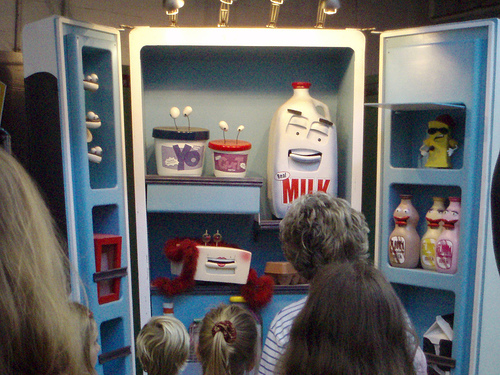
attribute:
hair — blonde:
[196, 301, 260, 374]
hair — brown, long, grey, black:
[274, 259, 417, 374]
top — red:
[290, 80, 314, 90]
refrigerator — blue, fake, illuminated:
[19, 17, 500, 374]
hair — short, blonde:
[277, 185, 372, 283]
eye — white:
[285, 113, 312, 141]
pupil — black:
[294, 130, 301, 136]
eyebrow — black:
[286, 108, 304, 119]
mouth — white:
[288, 148, 322, 164]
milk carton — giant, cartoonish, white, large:
[263, 79, 340, 221]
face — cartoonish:
[282, 105, 335, 174]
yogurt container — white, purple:
[154, 104, 210, 179]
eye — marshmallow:
[183, 104, 194, 131]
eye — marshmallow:
[167, 104, 181, 132]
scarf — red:
[150, 235, 277, 312]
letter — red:
[282, 176, 300, 207]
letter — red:
[300, 176, 309, 202]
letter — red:
[308, 179, 314, 199]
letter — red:
[315, 178, 333, 197]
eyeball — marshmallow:
[218, 118, 230, 143]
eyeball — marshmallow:
[234, 123, 248, 144]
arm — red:
[156, 237, 202, 297]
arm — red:
[242, 268, 276, 306]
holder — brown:
[211, 319, 238, 345]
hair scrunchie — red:
[211, 317, 239, 347]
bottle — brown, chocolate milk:
[386, 190, 422, 271]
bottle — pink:
[434, 191, 461, 274]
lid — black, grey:
[151, 126, 213, 144]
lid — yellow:
[430, 192, 447, 204]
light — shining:
[398, 27, 459, 82]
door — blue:
[373, 19, 500, 373]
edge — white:
[124, 23, 368, 339]